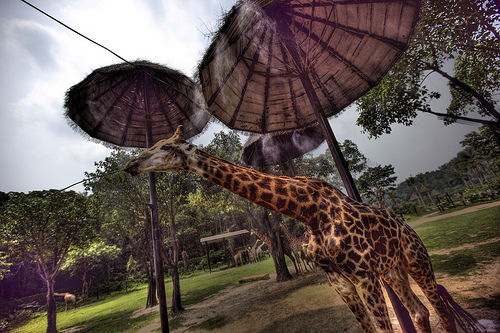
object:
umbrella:
[198, 0, 423, 134]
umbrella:
[63, 59, 210, 152]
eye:
[161, 143, 172, 150]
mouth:
[122, 164, 139, 177]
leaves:
[10, 191, 36, 211]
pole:
[278, 16, 417, 333]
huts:
[425, 189, 438, 211]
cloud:
[8, 26, 57, 91]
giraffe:
[250, 226, 300, 276]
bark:
[279, 216, 307, 282]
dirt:
[430, 205, 478, 222]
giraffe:
[54, 292, 77, 312]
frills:
[80, 131, 85, 135]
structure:
[199, 229, 250, 274]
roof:
[200, 229, 249, 246]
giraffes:
[251, 239, 260, 263]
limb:
[415, 106, 498, 126]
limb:
[436, 68, 500, 119]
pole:
[204, 241, 212, 274]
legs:
[403, 237, 457, 333]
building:
[127, 188, 313, 311]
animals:
[278, 211, 303, 276]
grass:
[134, 271, 224, 299]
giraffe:
[123, 124, 489, 332]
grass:
[97, 298, 127, 330]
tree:
[2, 189, 103, 330]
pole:
[142, 87, 168, 332]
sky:
[394, 128, 445, 163]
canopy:
[200, 229, 251, 275]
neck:
[196, 147, 309, 226]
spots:
[259, 190, 276, 203]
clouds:
[129, 2, 205, 66]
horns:
[175, 123, 186, 139]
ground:
[7, 198, 497, 332]